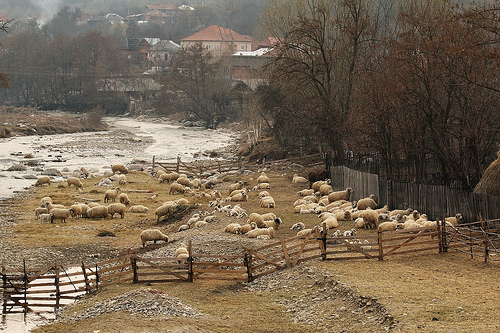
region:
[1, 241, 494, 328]
a small wooden fence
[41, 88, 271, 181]
a body of water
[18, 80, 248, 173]
rocks in a body of water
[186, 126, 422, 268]
sheep laying down on the ground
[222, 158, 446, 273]
sheep laying down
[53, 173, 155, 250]
sheep eating grass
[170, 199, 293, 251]
baby sheep laying down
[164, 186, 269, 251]
baby sheep laying down on the ground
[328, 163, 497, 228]
a big wooden fence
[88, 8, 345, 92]
buildings behind a fence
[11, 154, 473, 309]
several sheep within a fence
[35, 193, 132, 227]
several sheep eating hay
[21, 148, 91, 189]
several sheep beside the water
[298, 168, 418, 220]
several sheep along a fence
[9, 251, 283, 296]
a crooked wooden fence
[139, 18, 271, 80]
several buildings on a hillside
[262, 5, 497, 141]
several trees in a row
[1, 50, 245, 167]
a small river along a wooded area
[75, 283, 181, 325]
a large pile of rocks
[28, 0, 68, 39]
smoke rising from the trees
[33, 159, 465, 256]
a pen full of sheep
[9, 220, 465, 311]
a wooden fenced in pen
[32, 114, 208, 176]
a stream of running water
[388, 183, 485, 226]
a gray wooden fence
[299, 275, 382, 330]
a rocky bank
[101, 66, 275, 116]
buildings in the distance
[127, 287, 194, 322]
a rocky mound of grass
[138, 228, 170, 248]
a sheep eating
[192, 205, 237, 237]
sheep sleeping on the rocks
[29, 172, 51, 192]
a sheep drinking water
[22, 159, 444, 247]
Many sheep are grazing.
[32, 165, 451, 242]
The sheep are in the fence.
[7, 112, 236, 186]
The river has rushing water.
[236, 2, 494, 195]
The trees are bare.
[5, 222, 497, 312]
The fence is wood.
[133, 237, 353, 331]
The ground has rocks.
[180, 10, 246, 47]
The roof is red.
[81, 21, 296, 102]
The houses are covered by the trees.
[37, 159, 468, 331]
The grass is dead.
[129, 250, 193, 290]
a wooden gate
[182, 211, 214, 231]
lambs asleep on rocks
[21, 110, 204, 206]
a stream of water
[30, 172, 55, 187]
a lamb drinking water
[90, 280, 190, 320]
a pile of stones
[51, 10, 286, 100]
a town in the distance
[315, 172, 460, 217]
a gray wooden fence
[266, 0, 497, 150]
leaf less trees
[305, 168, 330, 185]
a brown horse by the fence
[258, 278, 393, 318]
a bank of rock